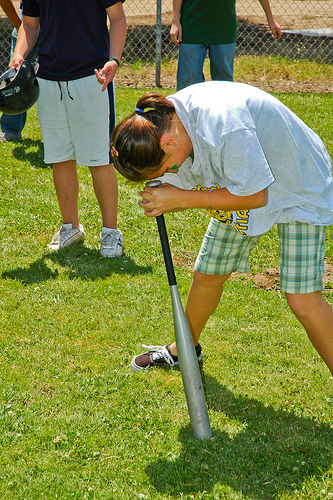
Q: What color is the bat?
A: Black and silver.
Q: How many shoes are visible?
A: 4.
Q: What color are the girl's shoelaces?
A: White.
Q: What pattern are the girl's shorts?
A: Plaid.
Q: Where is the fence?
A: Background.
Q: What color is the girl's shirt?
A: Grey.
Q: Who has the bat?
A: The girl.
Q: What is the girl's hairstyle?
A: Ponytail.